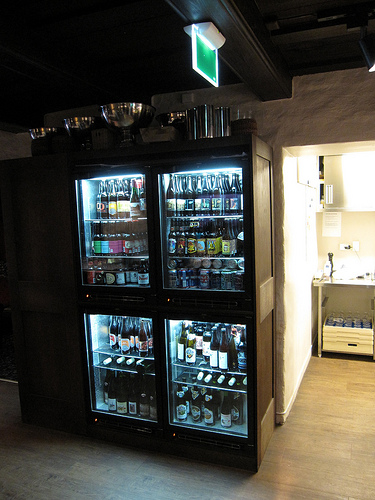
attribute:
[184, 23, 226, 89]
sign — green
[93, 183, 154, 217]
beer — bottles of beer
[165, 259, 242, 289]
cans — aluminum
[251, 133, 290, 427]
door — wooden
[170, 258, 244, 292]
cans — soda cans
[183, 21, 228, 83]
light — green 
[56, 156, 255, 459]
refrigerator — beer refrigerator, standing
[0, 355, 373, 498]
floor — wooden, finished floor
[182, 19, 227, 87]
signage — hanging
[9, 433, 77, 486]
floor — wooden, light brown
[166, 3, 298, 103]
beams — created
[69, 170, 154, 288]
door — black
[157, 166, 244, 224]
beverages — alcoholic beverages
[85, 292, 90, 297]
light — small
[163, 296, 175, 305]
light — small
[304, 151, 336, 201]
cabinet — silver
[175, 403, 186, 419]
lable — white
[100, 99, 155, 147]
pot — round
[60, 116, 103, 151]
pot — round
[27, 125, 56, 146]
pot — round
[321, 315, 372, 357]
drawer — brown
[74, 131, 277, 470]
cooler — metal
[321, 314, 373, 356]
crate — wooden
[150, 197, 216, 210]
label — white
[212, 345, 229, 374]
label — white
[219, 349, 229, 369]
label — white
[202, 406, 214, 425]
label — white